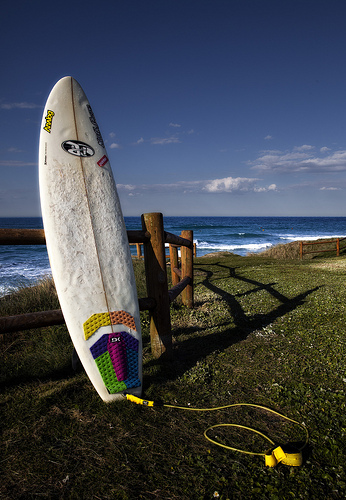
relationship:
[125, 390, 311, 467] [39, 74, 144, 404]
strap connected to surfboard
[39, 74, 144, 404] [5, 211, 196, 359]
surfboard against fence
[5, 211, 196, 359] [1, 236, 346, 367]
fence surround beach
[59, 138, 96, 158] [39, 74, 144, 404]
pattern on surfboard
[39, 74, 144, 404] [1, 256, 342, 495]
surfboard on grass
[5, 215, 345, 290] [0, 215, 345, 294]
water in ocean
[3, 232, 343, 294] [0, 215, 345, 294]
whitecaps in ocean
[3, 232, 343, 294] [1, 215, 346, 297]
whitecaps from waves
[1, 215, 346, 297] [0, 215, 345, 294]
waves in ocean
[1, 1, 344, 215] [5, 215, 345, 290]
sky above water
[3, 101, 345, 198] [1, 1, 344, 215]
clouds in sky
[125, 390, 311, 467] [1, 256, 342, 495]
strap on grass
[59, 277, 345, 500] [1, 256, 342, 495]
flowers in grass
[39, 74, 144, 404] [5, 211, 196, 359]
surfboard on fence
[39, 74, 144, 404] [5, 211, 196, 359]
surfboard leaning on fence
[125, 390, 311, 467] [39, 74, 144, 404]
strap attached to surfboard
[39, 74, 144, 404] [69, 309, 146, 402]
surfboard has end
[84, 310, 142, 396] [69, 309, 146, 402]
patches on end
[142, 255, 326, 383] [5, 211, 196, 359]
shadows of fence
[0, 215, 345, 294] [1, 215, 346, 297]
ocean has waves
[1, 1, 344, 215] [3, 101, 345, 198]
sky has clouds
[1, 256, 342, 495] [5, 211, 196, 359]
grass behind fence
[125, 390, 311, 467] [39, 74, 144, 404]
strap on surfboard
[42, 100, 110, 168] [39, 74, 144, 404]
stickers on surfboard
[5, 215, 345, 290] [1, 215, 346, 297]
water with waves